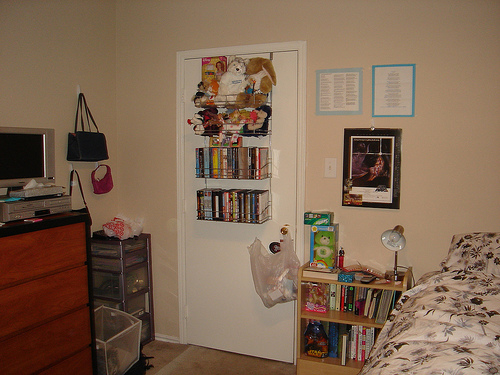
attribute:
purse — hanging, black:
[67, 92, 111, 163]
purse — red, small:
[91, 164, 114, 195]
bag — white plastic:
[248, 224, 302, 308]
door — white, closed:
[183, 48, 300, 364]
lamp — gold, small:
[381, 224, 407, 281]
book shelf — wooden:
[296, 259, 414, 373]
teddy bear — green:
[310, 222, 340, 268]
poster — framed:
[343, 127, 404, 210]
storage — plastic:
[89, 232, 156, 346]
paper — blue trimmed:
[316, 66, 364, 117]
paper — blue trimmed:
[371, 63, 416, 118]